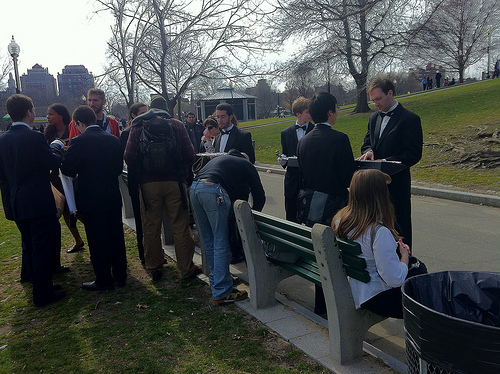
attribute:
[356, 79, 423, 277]
man — playing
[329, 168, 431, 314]
woman — sitting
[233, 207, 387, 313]
bench — green, concrete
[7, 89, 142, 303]
people — standing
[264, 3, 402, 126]
tree — leafless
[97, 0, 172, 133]
tree — leafless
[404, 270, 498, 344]
bag — black, plastic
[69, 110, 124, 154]
jacket — red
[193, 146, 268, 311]
man — bending, leaning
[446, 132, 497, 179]
roots — brown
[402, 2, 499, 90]
tree — leafless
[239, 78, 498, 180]
grass — green